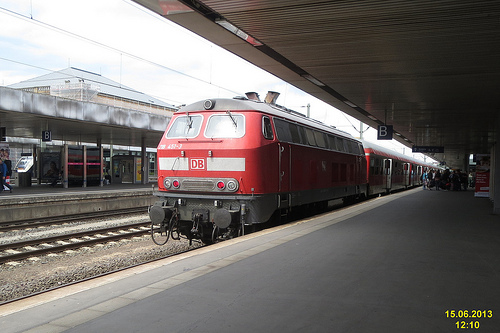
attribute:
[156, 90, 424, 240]
train — red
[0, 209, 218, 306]
ground — gravel covered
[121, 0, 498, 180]
roof — Silver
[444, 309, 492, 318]
date — Yellow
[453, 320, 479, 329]
time — Yellow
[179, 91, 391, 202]
train — red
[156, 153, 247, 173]
line — white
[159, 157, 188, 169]
patch — white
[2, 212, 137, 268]
tracks — railroad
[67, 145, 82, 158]
window — Clear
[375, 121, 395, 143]
sign — Hanging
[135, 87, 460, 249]
train — red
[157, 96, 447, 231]
train — Stationary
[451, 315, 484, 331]
time — Yellow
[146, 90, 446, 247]
train — red, passenger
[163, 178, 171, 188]
headlight — round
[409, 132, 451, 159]
sign — Hanging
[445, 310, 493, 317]
date — Yellow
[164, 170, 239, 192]
headlight — round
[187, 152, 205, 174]
letter — red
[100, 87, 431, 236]
train — red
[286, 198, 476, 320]
platform — covered